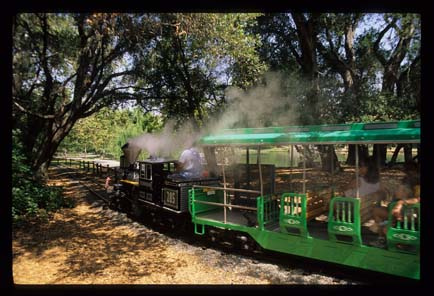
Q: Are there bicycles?
A: No, there are no bicycles.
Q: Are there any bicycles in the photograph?
A: No, there are no bicycles.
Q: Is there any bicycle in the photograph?
A: No, there are no bicycles.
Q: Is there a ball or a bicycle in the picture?
A: No, there are no bicycles or balls.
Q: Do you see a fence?
A: Yes, there is a fence.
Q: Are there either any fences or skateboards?
A: Yes, there is a fence.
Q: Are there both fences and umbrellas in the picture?
A: No, there is a fence but no umbrellas.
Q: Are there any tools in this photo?
A: No, there are no tools.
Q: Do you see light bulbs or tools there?
A: No, there are no tools or light bulbs.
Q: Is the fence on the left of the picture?
A: Yes, the fence is on the left of the image.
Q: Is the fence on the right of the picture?
A: No, the fence is on the left of the image.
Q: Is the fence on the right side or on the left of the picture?
A: The fence is on the left of the image.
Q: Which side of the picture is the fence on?
A: The fence is on the left of the image.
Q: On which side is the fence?
A: The fence is on the left of the image.